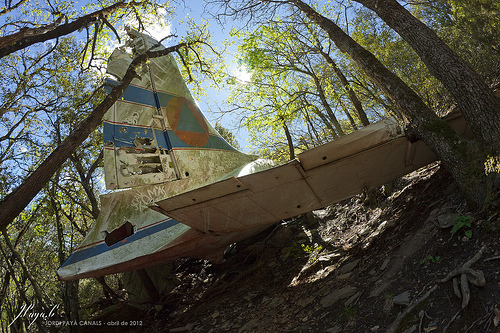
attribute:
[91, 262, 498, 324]
dirt — brown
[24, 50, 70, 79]
sky — bright blue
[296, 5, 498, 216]
trunks — tall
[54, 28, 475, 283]
plane — crashed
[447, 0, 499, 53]
leaves — green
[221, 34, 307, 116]
faleaves — light green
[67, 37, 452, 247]
boat — small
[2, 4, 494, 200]
sky — blue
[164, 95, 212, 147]
circle — orange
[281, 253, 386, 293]
dirt — brown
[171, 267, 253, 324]
dirt — brown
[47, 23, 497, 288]
remains — crashed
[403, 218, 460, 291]
greenery — growing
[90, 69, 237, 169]
stripes — blue